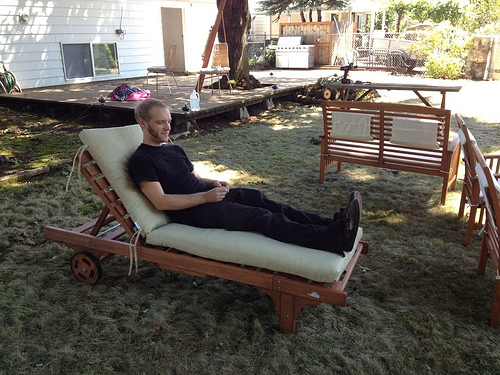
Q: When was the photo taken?
A: Day time.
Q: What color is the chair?
A: Brown.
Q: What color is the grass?
A: Green.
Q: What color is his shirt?
A: Black.